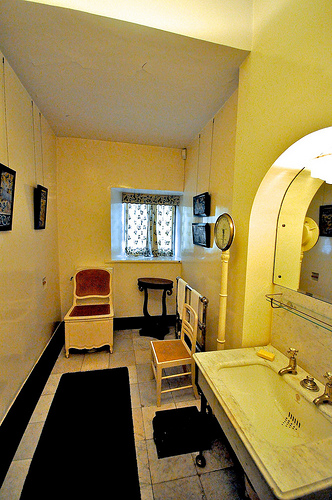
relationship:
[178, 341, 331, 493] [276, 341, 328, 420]
sink has faucet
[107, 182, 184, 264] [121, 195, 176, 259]
window has curtain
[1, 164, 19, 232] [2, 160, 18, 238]
picture with frame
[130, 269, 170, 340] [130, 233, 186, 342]
table in corner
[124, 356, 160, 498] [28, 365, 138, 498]
tile has rug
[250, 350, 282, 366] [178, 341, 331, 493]
soap on sink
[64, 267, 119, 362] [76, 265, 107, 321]
chair has cushions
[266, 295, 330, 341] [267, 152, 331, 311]
shelf under mirror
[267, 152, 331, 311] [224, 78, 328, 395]
mirror on wall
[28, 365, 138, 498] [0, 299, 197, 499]
rug on floor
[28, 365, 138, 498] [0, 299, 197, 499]
rug covers floor